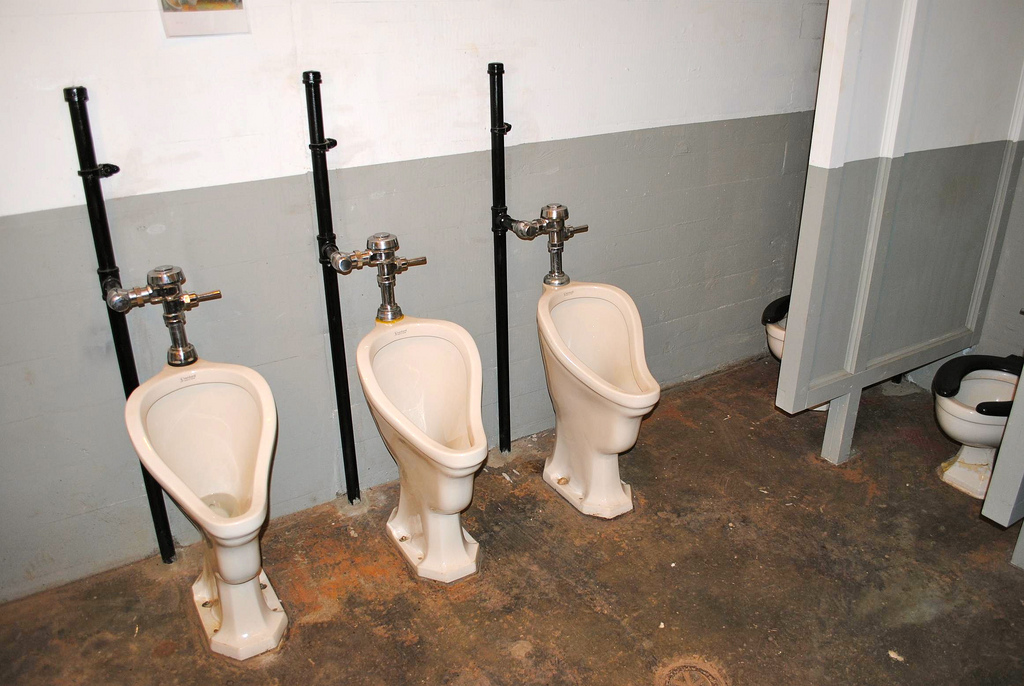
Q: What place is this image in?
A: It is at the restroom.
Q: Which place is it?
A: It is a restroom.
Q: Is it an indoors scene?
A: Yes, it is indoors.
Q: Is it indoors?
A: Yes, it is indoors.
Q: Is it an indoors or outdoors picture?
A: It is indoors.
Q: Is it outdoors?
A: No, it is indoors.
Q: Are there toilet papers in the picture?
A: No, there are no toilet papers.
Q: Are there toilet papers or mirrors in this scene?
A: No, there are no toilet papers or mirrors.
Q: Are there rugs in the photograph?
A: No, there are no rugs.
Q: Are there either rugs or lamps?
A: No, there are no rugs or lamps.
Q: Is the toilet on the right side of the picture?
A: Yes, the toilet is on the right of the image.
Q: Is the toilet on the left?
A: No, the toilet is on the right of the image.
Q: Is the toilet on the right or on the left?
A: The toilet is on the right of the image.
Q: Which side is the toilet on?
A: The toilet is on the right of the image.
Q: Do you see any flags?
A: No, there are no flags.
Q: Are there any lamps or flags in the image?
A: No, there are no flags or lamps.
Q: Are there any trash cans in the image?
A: No, there are no trash cans.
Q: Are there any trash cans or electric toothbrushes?
A: No, there are no trash cans or electric toothbrushes.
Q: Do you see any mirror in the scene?
A: No, there are no mirrors.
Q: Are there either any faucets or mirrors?
A: No, there are no mirrors or faucets.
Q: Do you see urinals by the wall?
A: Yes, there is a urinal by the wall.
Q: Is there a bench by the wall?
A: No, there is a urinal by the wall.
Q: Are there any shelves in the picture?
A: No, there are no shelves.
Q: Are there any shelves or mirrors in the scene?
A: No, there are no shelves or mirrors.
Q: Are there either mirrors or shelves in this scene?
A: No, there are no shelves or mirrors.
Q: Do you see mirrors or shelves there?
A: No, there are no shelves or mirrors.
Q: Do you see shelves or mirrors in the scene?
A: No, there are no shelves or mirrors.